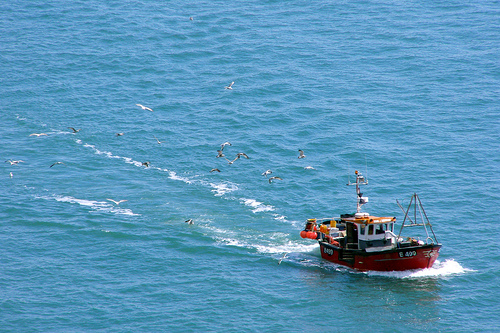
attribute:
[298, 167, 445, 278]
boat — red, white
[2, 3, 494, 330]
water — large, clear, blue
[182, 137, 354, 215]
buoys — orange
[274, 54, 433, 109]
water — splashing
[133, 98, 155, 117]
bird — white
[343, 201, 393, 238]
cabin — white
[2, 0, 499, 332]
ocean — blue, calm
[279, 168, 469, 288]
boat — red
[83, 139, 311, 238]
ripples — small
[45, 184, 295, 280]
ripples — small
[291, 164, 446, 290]
boat — red, white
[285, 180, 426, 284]
fishing boat — red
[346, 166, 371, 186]
area — lookout area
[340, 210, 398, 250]
cabin — white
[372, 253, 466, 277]
water splashing — white